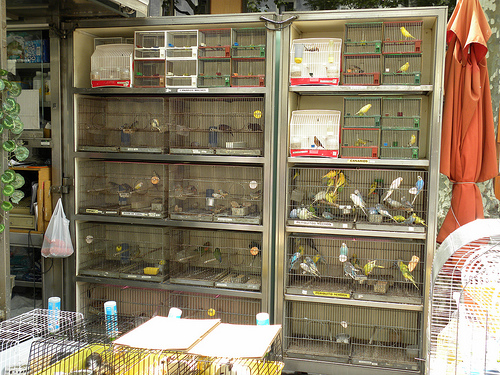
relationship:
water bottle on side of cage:
[44, 291, 64, 332] [1, 300, 86, 373]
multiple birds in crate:
[319, 168, 352, 210] [285, 166, 427, 238]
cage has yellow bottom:
[1, 300, 86, 373] [88, 341, 162, 374]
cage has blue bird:
[285, 166, 427, 238] [411, 173, 425, 206]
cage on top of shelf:
[77, 162, 168, 217] [72, 210, 268, 236]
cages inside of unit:
[80, 95, 263, 157] [60, 13, 272, 343]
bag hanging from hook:
[39, 192, 76, 261] [49, 178, 74, 197]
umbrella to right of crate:
[438, 1, 499, 238] [285, 166, 427, 238]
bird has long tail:
[394, 256, 421, 289] [403, 274, 422, 294]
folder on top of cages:
[111, 315, 223, 354] [29, 312, 284, 373]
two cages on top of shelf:
[74, 160, 265, 227] [72, 210, 268, 236]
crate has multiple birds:
[287, 233, 424, 307] [335, 243, 381, 283]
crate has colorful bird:
[287, 233, 424, 307] [289, 244, 306, 274]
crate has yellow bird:
[285, 166, 427, 238] [335, 171, 347, 191]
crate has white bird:
[285, 166, 427, 238] [382, 175, 403, 202]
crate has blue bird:
[287, 233, 424, 307] [335, 240, 351, 260]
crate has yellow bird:
[285, 166, 427, 238] [322, 167, 341, 180]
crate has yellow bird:
[285, 166, 427, 238] [324, 189, 341, 205]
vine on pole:
[2, 67, 29, 229] [1, 1, 14, 320]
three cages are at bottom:
[29, 312, 284, 373] [1, 299, 497, 373]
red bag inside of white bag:
[46, 231, 71, 260] [39, 192, 76, 261]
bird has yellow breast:
[115, 243, 121, 256] [116, 248, 126, 251]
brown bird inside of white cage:
[311, 130, 328, 152] [289, 105, 343, 157]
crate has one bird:
[382, 22, 423, 57] [395, 22, 419, 44]